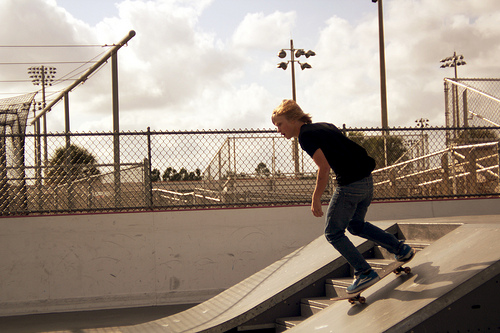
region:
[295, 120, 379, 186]
black tshirt on a skater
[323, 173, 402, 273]
jeans on a skater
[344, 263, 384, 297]
blue and white sneaker on a skater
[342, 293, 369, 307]
front wheels on a skateboard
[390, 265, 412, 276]
back wheels of a skateboard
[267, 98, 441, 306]
young boy skating on a ramp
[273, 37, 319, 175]
lights on a pole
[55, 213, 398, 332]
a skateboard ramp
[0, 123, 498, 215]
silver chainlink fence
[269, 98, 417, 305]
young boy on a skateboard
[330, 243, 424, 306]
Boy on a skateboard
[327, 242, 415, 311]
Boy is on a skateboard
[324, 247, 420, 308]
Boy riding a skateboard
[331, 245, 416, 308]
Boy is riding a skateboard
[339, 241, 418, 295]
Boy wearing shoes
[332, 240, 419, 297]
Boy is wearing shoes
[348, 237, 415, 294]
Boy wearing blue shoes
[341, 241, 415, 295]
Boy is wearing blue shoes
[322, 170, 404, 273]
Boy wearing blue jeans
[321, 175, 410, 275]
Boy is wearing blue jeans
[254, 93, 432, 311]
person skateboarding down ramp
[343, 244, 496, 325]
shadow of person on concrete ramp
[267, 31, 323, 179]
street kight on grey metal pole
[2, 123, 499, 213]
short chain link metal fence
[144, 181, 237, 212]
metal handrail for steps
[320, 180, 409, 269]
pair of blue jeans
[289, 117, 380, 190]
black short sleeve t-shirt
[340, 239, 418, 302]
blue and white sneakers on skateboard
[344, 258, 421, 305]
wheels on bottom of skateboard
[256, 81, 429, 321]
A young kid on a skateboard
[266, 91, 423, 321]
A side view of a kid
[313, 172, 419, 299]
Young kid is wearing jeans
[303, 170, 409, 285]
The jeans are blue in color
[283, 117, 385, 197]
Young boy is wearing a black shirt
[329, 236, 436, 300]
Young boy is wearing blue shoes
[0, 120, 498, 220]
A chain link fence in the background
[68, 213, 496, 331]
A skateboard ramp in the foreground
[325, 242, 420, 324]
Top of the skateboard is dark gray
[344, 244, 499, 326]
Young boy is casting a shadow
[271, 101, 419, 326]
skateboarder goes down one side of a cement ramp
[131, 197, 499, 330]
cement stairs that are in center on cement ramp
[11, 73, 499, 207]
several areas separated by chain link fences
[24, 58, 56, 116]
overhead bright stadium lighting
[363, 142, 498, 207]
steel railings throughout the park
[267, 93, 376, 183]
blond boy wears a black shirt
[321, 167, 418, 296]
blue jeans worn with sneakers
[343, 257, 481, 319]
shadow of skateboard and skateboarder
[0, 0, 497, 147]
sunny day with increasing clouds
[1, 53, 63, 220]
a tarp strung up and pulled taut